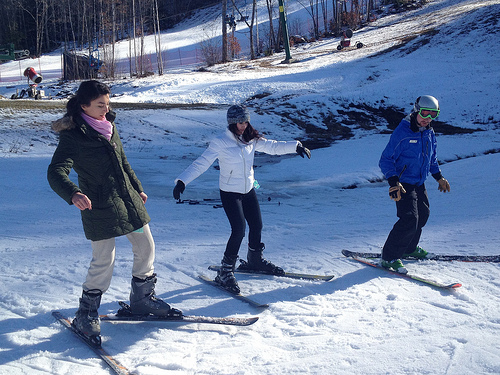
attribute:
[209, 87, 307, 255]
girl — young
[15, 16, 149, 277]
woman — skiing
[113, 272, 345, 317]
ski — black, here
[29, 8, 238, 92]
tree — here, narrow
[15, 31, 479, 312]
people — skiing, learning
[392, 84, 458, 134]
googles — green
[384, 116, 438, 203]
jacket — blue, white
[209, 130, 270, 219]
jacket — white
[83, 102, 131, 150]
scarf — pink, layered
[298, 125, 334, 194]
glove — tan, black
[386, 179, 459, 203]
gloves — tan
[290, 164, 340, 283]
snow — here, white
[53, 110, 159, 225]
coat — black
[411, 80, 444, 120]
helmet — silver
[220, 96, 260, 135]
cap — grey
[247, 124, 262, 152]
hair — black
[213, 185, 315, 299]
pants — black